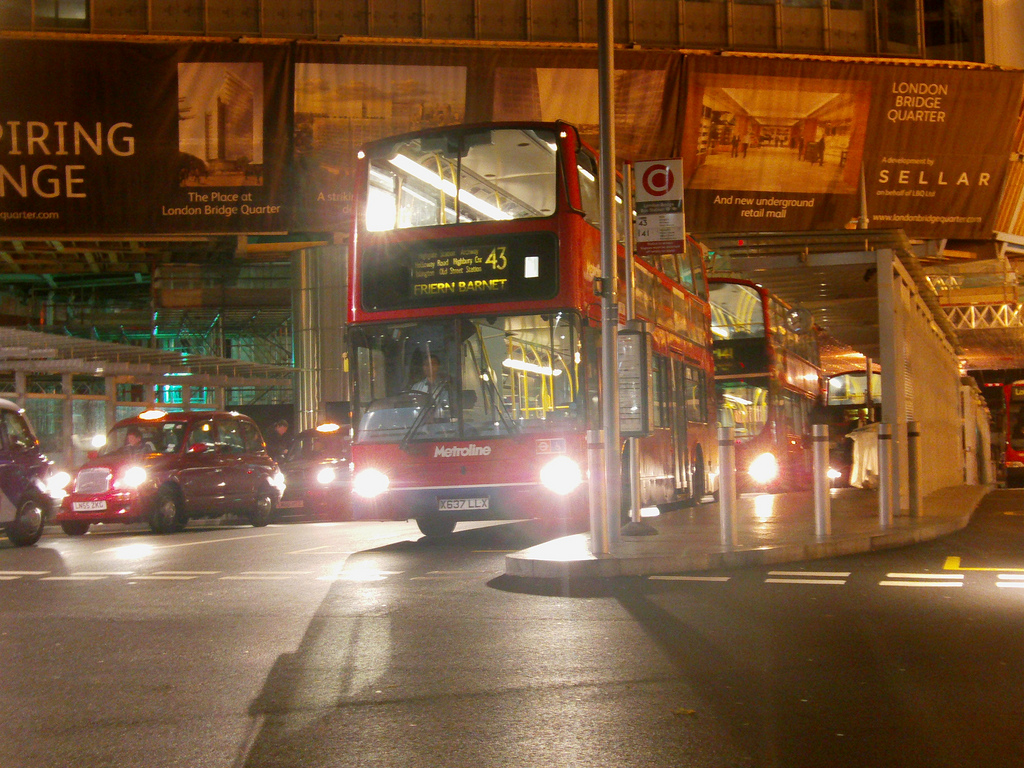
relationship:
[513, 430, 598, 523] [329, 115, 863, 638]
light on bus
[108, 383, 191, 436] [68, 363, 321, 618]
light on bus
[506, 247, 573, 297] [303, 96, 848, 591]
light on bus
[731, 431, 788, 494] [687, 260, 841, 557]
light on bus